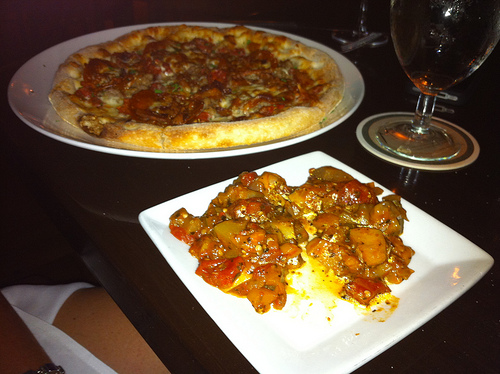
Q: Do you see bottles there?
A: No, there are no bottles.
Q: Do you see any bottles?
A: No, there are no bottles.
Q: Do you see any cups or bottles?
A: No, there are no bottles or cups.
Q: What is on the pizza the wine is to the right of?
A: The sauce is on the pizza.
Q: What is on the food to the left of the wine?
A: The sauce is on the pizza.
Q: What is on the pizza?
A: The sauce is on the pizza.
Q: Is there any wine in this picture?
A: Yes, there is wine.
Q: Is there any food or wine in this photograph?
A: Yes, there is wine.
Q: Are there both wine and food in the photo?
A: Yes, there are both wine and food.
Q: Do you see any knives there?
A: No, there are no knives.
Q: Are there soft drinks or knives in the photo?
A: No, there are no knives or soft drinks.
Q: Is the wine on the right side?
A: Yes, the wine is on the right of the image.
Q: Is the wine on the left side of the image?
A: No, the wine is on the right of the image.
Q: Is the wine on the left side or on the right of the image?
A: The wine is on the right of the image.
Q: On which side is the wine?
A: The wine is on the right of the image.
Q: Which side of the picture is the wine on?
A: The wine is on the right of the image.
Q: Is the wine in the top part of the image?
A: Yes, the wine is in the top of the image.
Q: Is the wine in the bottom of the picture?
A: No, the wine is in the top of the image.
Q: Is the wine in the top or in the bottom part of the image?
A: The wine is in the top of the image.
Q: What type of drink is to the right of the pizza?
A: The drink is wine.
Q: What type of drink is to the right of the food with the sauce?
A: The drink is wine.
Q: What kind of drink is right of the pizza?
A: The drink is wine.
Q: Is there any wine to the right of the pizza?
A: Yes, there is wine to the right of the pizza.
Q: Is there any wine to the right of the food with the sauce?
A: Yes, there is wine to the right of the pizza.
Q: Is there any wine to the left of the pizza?
A: No, the wine is to the right of the pizza.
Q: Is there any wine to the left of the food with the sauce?
A: No, the wine is to the right of the pizza.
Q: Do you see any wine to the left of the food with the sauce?
A: No, the wine is to the right of the pizza.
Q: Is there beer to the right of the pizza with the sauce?
A: No, there is wine to the right of the pizza.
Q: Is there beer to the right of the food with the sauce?
A: No, there is wine to the right of the pizza.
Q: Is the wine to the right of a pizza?
A: Yes, the wine is to the right of a pizza.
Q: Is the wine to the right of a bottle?
A: No, the wine is to the right of a pizza.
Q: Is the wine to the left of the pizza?
A: No, the wine is to the right of the pizza.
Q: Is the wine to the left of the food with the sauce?
A: No, the wine is to the right of the pizza.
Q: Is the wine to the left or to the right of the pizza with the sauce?
A: The wine is to the right of the pizza.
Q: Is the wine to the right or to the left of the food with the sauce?
A: The wine is to the right of the pizza.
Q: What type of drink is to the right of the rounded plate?
A: The drink is wine.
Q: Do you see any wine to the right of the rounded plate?
A: Yes, there is wine to the right of the plate.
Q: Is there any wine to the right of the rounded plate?
A: Yes, there is wine to the right of the plate.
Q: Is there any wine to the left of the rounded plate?
A: No, the wine is to the right of the plate.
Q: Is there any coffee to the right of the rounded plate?
A: No, there is wine to the right of the plate.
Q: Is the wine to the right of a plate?
A: Yes, the wine is to the right of a plate.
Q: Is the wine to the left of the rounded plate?
A: No, the wine is to the right of the plate.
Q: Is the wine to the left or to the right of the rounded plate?
A: The wine is to the right of the plate.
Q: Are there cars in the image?
A: No, there are no cars.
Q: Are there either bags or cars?
A: No, there are no cars or bags.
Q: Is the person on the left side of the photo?
A: Yes, the person is on the left of the image.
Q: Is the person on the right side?
A: No, the person is on the left of the image.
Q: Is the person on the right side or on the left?
A: The person is on the left of the image.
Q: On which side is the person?
A: The person is on the left of the image.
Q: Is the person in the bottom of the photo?
A: Yes, the person is in the bottom of the image.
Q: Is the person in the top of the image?
A: No, the person is in the bottom of the image.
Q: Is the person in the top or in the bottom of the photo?
A: The person is in the bottom of the image.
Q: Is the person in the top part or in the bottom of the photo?
A: The person is in the bottom of the image.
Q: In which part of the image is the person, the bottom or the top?
A: The person is in the bottom of the image.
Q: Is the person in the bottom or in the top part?
A: The person is in the bottom of the image.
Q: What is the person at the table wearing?
A: The person is wearing a wristwatch.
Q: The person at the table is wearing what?
A: The person is wearing a wristwatch.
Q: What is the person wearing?
A: The person is wearing a wristwatch.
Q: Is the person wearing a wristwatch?
A: Yes, the person is wearing a wristwatch.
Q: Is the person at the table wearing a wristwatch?
A: Yes, the person is wearing a wristwatch.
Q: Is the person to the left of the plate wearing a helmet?
A: No, the person is wearing a wristwatch.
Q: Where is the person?
A: The person is at the table.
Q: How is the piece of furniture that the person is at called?
A: The piece of furniture is a table.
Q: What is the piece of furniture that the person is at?
A: The piece of furniture is a table.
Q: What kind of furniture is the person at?
A: The person is at the table.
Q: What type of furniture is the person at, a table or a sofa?
A: The person is at a table.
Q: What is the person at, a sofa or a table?
A: The person is at a table.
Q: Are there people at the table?
A: Yes, there is a person at the table.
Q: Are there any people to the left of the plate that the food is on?
A: Yes, there is a person to the left of the plate.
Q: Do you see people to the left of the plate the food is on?
A: Yes, there is a person to the left of the plate.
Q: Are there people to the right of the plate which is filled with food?
A: No, the person is to the left of the plate.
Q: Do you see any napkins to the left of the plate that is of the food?
A: No, there is a person to the left of the plate.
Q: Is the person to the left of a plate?
A: Yes, the person is to the left of a plate.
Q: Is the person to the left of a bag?
A: No, the person is to the left of a plate.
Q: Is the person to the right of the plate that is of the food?
A: No, the person is to the left of the plate.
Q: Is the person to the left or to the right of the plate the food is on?
A: The person is to the left of the plate.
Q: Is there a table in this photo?
A: Yes, there is a table.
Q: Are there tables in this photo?
A: Yes, there is a table.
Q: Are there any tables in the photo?
A: Yes, there is a table.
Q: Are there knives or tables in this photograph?
A: Yes, there is a table.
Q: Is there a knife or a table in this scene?
A: Yes, there is a table.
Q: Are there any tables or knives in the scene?
A: Yes, there is a table.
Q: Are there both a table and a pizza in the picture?
A: Yes, there are both a table and a pizza.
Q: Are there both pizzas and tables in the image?
A: Yes, there are both a table and a pizza.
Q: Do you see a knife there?
A: No, there are no knives.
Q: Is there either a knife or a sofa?
A: No, there are no knives or sofas.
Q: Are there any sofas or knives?
A: No, there are no knives or sofas.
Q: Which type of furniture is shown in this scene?
A: The furniture is a table.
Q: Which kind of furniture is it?
A: The piece of furniture is a table.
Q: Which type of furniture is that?
A: This is a table.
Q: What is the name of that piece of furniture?
A: This is a table.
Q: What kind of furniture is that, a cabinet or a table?
A: This is a table.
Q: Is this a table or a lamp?
A: This is a table.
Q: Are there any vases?
A: No, there are no vases.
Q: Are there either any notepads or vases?
A: No, there are no vases or notepads.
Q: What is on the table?
A: The glass is on the table.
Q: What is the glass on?
A: The glass is on the table.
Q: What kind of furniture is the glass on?
A: The glass is on the table.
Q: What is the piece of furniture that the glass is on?
A: The piece of furniture is a table.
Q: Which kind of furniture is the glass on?
A: The glass is on the table.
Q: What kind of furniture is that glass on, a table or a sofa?
A: The glass is on a table.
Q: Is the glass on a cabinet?
A: No, the glass is on the table.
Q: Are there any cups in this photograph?
A: No, there are no cups.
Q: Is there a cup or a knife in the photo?
A: No, there are no cups or knives.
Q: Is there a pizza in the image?
A: Yes, there is a pizza.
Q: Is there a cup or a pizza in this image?
A: Yes, there is a pizza.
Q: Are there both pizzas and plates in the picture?
A: Yes, there are both a pizza and a plate.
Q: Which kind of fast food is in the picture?
A: The fast food is a pizza.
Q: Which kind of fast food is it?
A: The food is a pizza.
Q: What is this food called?
A: This is a pizza.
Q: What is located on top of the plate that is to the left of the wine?
A: The pizza is on top of the plate.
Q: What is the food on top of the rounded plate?
A: The food is a pizza.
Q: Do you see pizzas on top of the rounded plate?
A: Yes, there is a pizza on top of the plate.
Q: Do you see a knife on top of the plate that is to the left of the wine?
A: No, there is a pizza on top of the plate.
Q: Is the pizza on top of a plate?
A: Yes, the pizza is on top of a plate.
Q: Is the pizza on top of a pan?
A: No, the pizza is on top of a plate.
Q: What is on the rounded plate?
A: The pizza is on the plate.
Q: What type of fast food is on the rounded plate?
A: The food is a pizza.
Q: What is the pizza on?
A: The pizza is on the plate.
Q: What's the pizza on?
A: The pizza is on the plate.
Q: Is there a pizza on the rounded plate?
A: Yes, there is a pizza on the plate.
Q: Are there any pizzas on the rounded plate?
A: Yes, there is a pizza on the plate.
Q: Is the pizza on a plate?
A: Yes, the pizza is on a plate.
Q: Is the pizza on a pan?
A: No, the pizza is on a plate.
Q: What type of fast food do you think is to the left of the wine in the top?
A: The food is a pizza.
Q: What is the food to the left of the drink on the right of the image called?
A: The food is a pizza.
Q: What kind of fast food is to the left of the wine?
A: The food is a pizza.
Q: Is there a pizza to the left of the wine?
A: Yes, there is a pizza to the left of the wine.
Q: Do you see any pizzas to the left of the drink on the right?
A: Yes, there is a pizza to the left of the wine.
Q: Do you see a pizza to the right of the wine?
A: No, the pizza is to the left of the wine.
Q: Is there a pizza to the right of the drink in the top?
A: No, the pizza is to the left of the wine.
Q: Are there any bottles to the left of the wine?
A: No, there is a pizza to the left of the wine.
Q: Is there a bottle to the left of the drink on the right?
A: No, there is a pizza to the left of the wine.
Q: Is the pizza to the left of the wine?
A: Yes, the pizza is to the left of the wine.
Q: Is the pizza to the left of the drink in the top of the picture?
A: Yes, the pizza is to the left of the wine.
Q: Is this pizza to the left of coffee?
A: No, the pizza is to the left of the wine.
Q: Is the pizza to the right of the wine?
A: No, the pizza is to the left of the wine.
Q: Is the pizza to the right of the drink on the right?
A: No, the pizza is to the left of the wine.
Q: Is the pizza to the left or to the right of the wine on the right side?
A: The pizza is to the left of the wine.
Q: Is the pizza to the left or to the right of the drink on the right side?
A: The pizza is to the left of the wine.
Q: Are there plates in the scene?
A: Yes, there is a plate.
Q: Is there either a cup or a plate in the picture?
A: Yes, there is a plate.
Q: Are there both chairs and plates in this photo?
A: No, there is a plate but no chairs.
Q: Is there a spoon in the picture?
A: No, there are no spoons.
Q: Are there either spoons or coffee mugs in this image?
A: No, there are no spoons or coffee mugs.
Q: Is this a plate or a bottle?
A: This is a plate.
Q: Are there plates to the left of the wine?
A: Yes, there is a plate to the left of the wine.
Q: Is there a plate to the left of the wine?
A: Yes, there is a plate to the left of the wine.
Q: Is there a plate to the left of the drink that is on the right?
A: Yes, there is a plate to the left of the wine.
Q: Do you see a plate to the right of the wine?
A: No, the plate is to the left of the wine.